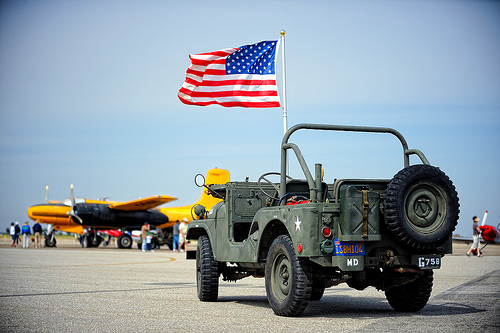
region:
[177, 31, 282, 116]
American flag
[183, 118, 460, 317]
Vintage looking Jeep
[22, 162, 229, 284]
Plane on the ground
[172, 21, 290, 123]
American flag flying in the wind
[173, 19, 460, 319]
Jeep in front of American flag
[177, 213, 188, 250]
Man with hat, white shirt, and khaki pants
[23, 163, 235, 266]
Yellow plane on the ground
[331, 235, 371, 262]
Blue license plate on vehicle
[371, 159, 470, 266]
Tire on the back of a vehicle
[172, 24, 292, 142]
American flag on pole flying in the wind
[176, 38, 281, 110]
red, white and blue flag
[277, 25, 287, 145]
silver pole holding up the flag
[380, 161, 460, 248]
black tire on the back of the jeep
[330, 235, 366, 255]
blue and yellow license plate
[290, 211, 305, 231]
white star on the jeep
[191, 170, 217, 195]
side mirror on the jeep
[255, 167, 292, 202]
steering wheel in the jeep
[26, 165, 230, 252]
yellow and black airplane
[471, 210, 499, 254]
white and red airplane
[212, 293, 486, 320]
the jeep's shadow on the ground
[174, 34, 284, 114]
waving United States of America flag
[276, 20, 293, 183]
silver flag pole with decorative silver ball on top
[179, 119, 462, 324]
green military jeep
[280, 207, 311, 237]
white general's star on army jeep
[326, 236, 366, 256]
blue license plate with yellow lettering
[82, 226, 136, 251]
airplane's landing gear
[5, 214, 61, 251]
people standing next to yellow and black airplane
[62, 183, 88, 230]
airplane engine propellar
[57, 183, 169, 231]
black painted engine with propellar on yellow airplane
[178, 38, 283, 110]
red, white and blue American flag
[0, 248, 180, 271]
yellow line on the runway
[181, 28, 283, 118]
American flag blowing in wind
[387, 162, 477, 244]
spare tire on back of jeep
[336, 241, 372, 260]
blue license plate on back of truck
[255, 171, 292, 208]
steering wheel inside of truck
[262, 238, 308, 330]
left back tire on truck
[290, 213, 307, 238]
star design on side of truck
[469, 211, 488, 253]
person wearing white pants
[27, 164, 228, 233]
yellow airplane on runway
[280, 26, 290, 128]
silver flag pole outside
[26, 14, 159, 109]
clear blue sky outside